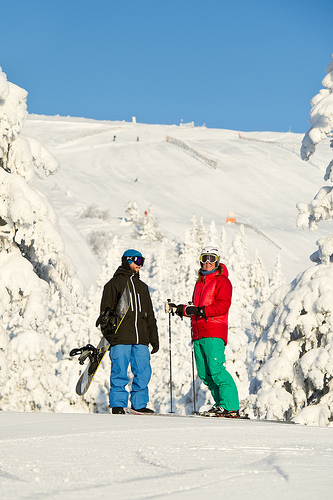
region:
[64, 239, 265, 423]
two skiers on a hill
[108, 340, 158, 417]
blue pants of skier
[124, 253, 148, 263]
goggles on skiers head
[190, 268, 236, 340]
red jacket of skier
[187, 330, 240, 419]
green pants on skier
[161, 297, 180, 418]
ski pole standing upright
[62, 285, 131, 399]
snow board held by male skier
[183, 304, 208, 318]
black glove on skiers hand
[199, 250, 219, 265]
goggles on female skier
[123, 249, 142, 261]
blue hat on skiers head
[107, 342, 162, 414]
blue pants on male skier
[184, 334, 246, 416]
green ppants of female skier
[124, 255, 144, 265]
goggle on male skier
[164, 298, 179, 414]
ski pole held by woman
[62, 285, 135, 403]
snow board held by man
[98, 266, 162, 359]
black jacket on man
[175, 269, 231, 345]
red jacket on woman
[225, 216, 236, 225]
flag in snow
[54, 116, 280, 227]
Four snow skiers on distant mountain course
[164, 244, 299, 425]
Skier on skis with poles at bottom of slope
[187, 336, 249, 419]
Bright green ski pants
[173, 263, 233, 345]
Red ski jacket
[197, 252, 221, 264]
sun shaded ski goggles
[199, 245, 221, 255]
White ski helmet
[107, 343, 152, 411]
Blue ski pants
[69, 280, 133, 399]
Single ski board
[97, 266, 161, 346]
Black ski jacket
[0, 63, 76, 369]
Snow-laden coniferous trees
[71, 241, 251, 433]
two men standing on snow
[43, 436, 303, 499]
lines in the snow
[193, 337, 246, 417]
man is wearing green pants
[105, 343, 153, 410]
man is wearing blue pants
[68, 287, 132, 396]
man holding a snowboard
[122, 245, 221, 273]
both men are wearing goggles over their eyes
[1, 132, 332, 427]
trees that are laden with snow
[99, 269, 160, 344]
white zippers on man's black jacket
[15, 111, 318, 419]
a high sloping mountain behind the two men in the foreground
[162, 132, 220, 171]
fencing on the slope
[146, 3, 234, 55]
this is the sky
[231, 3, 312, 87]
the sky is blue in color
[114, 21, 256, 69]
the sky is clear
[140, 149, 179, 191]
this is the ground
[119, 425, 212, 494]
the ground is full of snow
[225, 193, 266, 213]
this is the snow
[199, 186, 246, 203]
the snow is white in color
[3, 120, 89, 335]
these are some trees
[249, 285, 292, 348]
the leaves are covered with snow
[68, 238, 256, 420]
the two people are snowsurfing